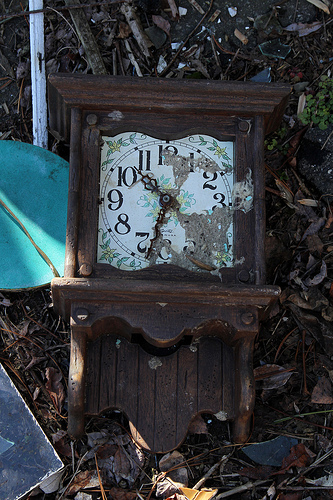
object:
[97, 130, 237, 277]
clock is on leaves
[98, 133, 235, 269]
clock is broken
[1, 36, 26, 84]
leaves are brown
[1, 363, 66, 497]
piece of glass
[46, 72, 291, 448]
piece of wood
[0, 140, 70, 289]
teal plate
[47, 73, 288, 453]
brown shelf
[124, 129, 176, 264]
time reads 10:35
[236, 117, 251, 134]
metal bolt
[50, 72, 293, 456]
turquoise board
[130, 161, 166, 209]
arms of a clock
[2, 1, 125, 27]
broken branch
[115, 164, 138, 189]
number on the clock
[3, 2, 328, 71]
part of the earth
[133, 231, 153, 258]
number seven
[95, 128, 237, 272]
web-like material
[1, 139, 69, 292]
blue object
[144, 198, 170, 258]
clock hands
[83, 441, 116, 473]
leaves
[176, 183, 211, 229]
pattern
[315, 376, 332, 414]
leaves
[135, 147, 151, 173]
number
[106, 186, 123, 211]
number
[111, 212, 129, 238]
number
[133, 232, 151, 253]
number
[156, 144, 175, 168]
number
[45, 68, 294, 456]
clock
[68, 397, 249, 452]
design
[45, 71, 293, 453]
clock stand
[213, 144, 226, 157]
flower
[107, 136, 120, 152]
flower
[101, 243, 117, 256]
flower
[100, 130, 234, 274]
clock face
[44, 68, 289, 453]
case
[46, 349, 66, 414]
leaves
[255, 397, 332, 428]
twigs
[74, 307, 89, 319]
peg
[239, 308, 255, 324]
peg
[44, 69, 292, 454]
clock frame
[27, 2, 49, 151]
molding